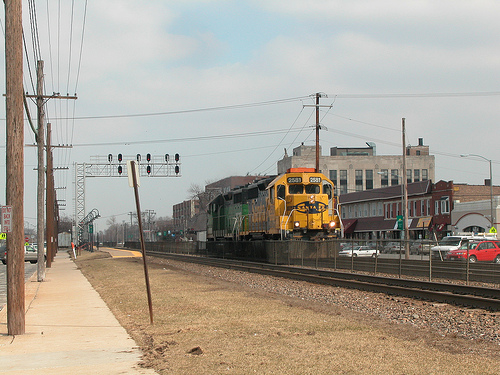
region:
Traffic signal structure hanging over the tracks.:
[75, 151, 189, 182]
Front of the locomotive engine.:
[257, 158, 345, 253]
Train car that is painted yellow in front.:
[255, 153, 348, 247]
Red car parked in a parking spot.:
[442, 236, 498, 267]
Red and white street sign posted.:
[0, 199, 25, 239]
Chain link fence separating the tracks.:
[355, 229, 465, 280]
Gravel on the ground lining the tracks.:
[346, 288, 375, 308]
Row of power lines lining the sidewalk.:
[20, 49, 72, 283]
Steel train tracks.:
[274, 260, 316, 284]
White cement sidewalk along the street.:
[57, 278, 87, 343]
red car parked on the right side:
[451, 220, 499, 272]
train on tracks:
[198, 163, 350, 267]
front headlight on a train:
[289, 217, 304, 231]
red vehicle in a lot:
[443, 238, 498, 270]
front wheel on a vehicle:
[466, 253, 478, 268]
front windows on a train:
[272, 179, 334, 203]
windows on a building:
[351, 164, 376, 194]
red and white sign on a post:
[0, 201, 18, 239]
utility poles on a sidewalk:
[25, 53, 77, 286]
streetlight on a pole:
[454, 148, 476, 162]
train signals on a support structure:
[93, 148, 188, 183]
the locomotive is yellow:
[215, 164, 364, 267]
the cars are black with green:
[201, 175, 253, 263]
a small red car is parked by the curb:
[454, 215, 497, 274]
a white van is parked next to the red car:
[426, 232, 467, 254]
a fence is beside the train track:
[200, 242, 465, 279]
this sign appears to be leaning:
[83, 141, 183, 322]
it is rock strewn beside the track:
[161, 253, 459, 358]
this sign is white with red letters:
[1, 201, 22, 247]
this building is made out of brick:
[356, 180, 460, 232]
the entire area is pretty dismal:
[126, 104, 481, 351]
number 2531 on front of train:
[281, 170, 309, 192]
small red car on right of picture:
[448, 241, 498, 263]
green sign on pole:
[393, 214, 417, 238]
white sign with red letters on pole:
[0, 199, 30, 246]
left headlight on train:
[288, 220, 306, 239]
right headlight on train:
[326, 218, 348, 240]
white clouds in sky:
[121, 28, 175, 82]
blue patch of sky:
[214, 6, 339, 73]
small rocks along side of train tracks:
[311, 277, 372, 319]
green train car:
[223, 192, 270, 255]